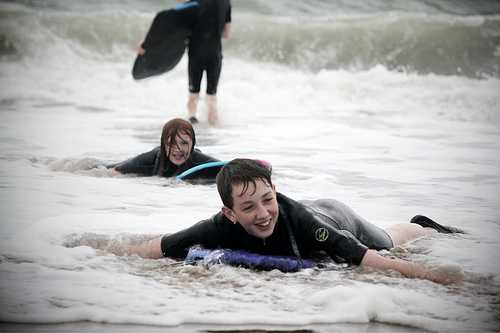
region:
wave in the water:
[388, 114, 413, 134]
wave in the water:
[372, 184, 404, 201]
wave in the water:
[290, 130, 315, 160]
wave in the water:
[405, 140, 445, 170]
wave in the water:
[248, 75, 264, 98]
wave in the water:
[147, 298, 177, 315]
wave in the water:
[59, 118, 86, 142]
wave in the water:
[292, 68, 322, 95]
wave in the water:
[38, 87, 69, 107]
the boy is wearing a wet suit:
[164, 178, 353, 299]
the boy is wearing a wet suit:
[108, 132, 375, 319]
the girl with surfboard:
[105, 97, 239, 203]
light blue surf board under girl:
[175, 154, 235, 179]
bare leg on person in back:
[203, 91, 226, 125]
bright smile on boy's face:
[250, 213, 288, 234]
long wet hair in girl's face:
[144, 107, 192, 180]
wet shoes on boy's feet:
[412, 208, 468, 257]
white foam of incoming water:
[310, 285, 381, 325]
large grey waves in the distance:
[298, 9, 444, 97]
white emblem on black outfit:
[313, 217, 338, 251]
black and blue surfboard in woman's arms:
[132, 6, 232, 104]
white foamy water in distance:
[334, 64, 441, 106]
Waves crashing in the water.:
[308, 15, 475, 164]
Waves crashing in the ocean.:
[304, 10, 480, 155]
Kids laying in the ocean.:
[102, 103, 442, 328]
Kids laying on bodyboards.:
[118, 115, 353, 328]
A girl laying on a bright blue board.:
[141, 105, 223, 194]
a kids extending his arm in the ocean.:
[93, 190, 458, 309]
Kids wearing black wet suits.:
[129, 103, 407, 316]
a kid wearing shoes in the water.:
[385, 198, 485, 262]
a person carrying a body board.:
[136, 9, 236, 87]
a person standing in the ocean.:
[140, 10, 286, 115]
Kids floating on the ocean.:
[121, 122, 326, 248]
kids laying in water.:
[142, 117, 379, 319]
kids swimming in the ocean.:
[127, 93, 379, 280]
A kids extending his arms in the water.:
[75, 183, 482, 298]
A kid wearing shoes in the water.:
[383, 190, 475, 252]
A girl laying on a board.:
[118, 109, 227, 201]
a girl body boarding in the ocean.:
[129, 103, 207, 202]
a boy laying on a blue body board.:
[168, 165, 348, 293]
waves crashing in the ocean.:
[307, 4, 453, 130]